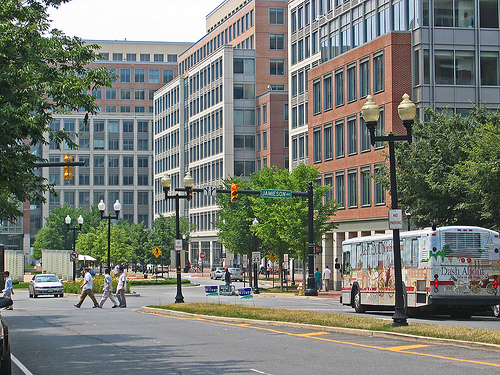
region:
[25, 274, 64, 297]
A white car at a traffic light.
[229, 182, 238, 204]
Yellow traffic light that is illuminted red.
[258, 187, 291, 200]
Green sign that says JAMESON.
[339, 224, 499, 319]
A mostly white long bus.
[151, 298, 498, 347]
Strip of green and yellow grass in the middle of the roads.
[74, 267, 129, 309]
Three men crossing the street together.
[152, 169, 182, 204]
this is a street light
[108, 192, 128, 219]
this is a street light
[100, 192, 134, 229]
this is a street light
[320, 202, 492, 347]
this is a bus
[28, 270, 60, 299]
this is a car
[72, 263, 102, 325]
this is a person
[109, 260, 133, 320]
this is a person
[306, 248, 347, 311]
this is a person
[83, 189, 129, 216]
pair of beautiful street light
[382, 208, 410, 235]
white sign on the post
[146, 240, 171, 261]
yellow sign with symbol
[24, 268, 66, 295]
white car on street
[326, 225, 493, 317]
passenger bus on the street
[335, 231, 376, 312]
bus on a street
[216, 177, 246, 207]
traffic light on a street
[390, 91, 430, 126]
light on a pole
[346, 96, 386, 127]
light on a pole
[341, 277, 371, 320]
tire on a bus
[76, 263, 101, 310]
man walking on street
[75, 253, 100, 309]
man wearing a shirt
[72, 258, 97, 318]
man wearing beige pants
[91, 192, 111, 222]
light on a pole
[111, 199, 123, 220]
light on a pole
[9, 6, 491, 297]
geometric office buildings in a city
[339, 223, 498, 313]
bus covered with scenes of horses and carriages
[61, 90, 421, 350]
lampposts with glass shades in street medians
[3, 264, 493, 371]
people crossing paved streets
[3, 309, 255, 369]
shadows of trees falling over street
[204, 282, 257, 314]
blue signs on wire supports on grass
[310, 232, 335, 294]
pedestrians walking in front of building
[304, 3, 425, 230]
brick panel with windows over gray building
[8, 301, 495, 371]
yellow and white stripes on street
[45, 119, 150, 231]
two lit windows in building if unlit windows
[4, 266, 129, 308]
people crossing the street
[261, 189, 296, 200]
green and white street sign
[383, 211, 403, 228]
red lettering on white sign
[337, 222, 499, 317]
bus driving down the street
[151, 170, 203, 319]
lamppost on a city street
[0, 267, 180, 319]
people walking across the street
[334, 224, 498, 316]
Cheerfully painted bus on the road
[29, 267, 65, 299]
White car on the road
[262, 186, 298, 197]
Street sign hanging from a post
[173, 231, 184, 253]
No parking sign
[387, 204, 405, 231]
No Parking sign on a post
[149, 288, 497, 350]
Grass island dividing street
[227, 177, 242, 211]
Traffic light showing red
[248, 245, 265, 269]
Speed limit sign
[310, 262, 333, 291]
Two people walking on the sidewalk